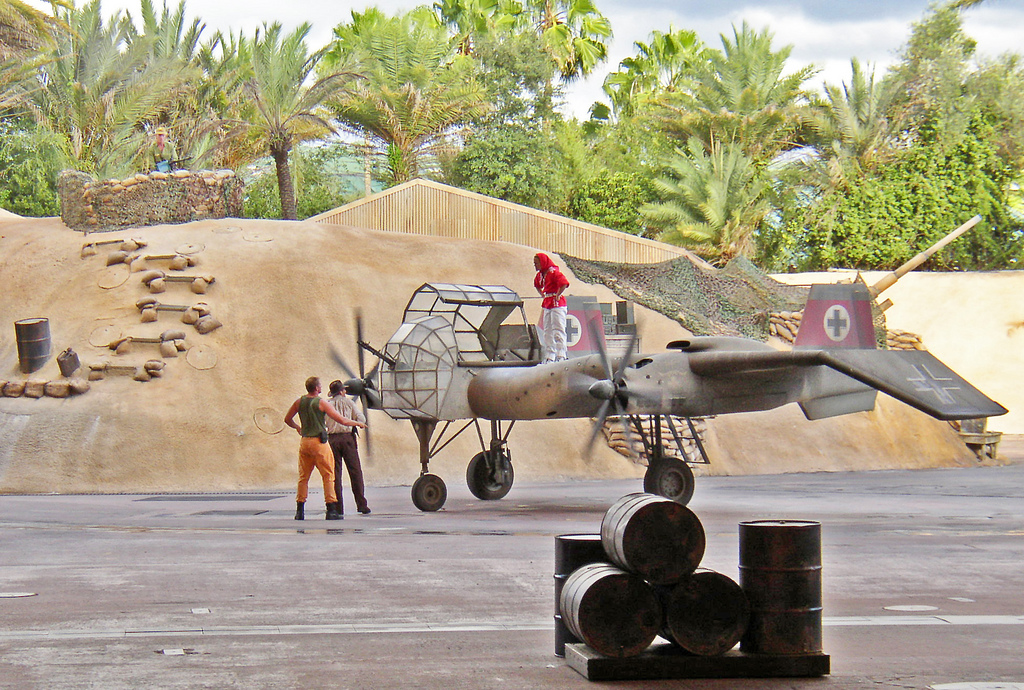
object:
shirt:
[298, 395, 326, 437]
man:
[284, 376, 371, 519]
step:
[88, 359, 165, 382]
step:
[110, 330, 190, 358]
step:
[140, 269, 216, 294]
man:
[534, 252, 570, 365]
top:
[532, 253, 568, 309]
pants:
[542, 296, 567, 358]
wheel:
[413, 475, 449, 514]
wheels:
[466, 449, 694, 510]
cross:
[822, 304, 850, 342]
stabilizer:
[791, 284, 878, 350]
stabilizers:
[673, 314, 1002, 429]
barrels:
[558, 491, 738, 654]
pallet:
[558, 642, 834, 683]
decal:
[824, 304, 852, 342]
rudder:
[792, 283, 877, 350]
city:
[0, 173, 1021, 690]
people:
[284, 255, 572, 521]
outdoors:
[0, 214, 1024, 690]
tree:
[325, 45, 505, 185]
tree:
[636, 127, 768, 272]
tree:
[770, 96, 1006, 271]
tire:
[411, 473, 447, 511]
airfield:
[0, 208, 1024, 690]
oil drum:
[737, 518, 822, 656]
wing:
[666, 337, 1009, 422]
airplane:
[328, 282, 1005, 511]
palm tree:
[194, 18, 363, 222]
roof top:
[293, 177, 688, 266]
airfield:
[0, 463, 1024, 689]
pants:
[295, 437, 345, 502]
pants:
[326, 431, 372, 497]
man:
[318, 379, 372, 514]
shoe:
[325, 503, 344, 521]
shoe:
[295, 502, 304, 520]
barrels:
[553, 491, 830, 681]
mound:
[0, 203, 977, 494]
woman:
[532, 252, 568, 366]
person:
[147, 127, 179, 171]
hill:
[0, 203, 999, 495]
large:
[789, 283, 1010, 420]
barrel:
[707, 274, 950, 435]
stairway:
[0, 235, 224, 398]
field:
[169, 203, 279, 221]